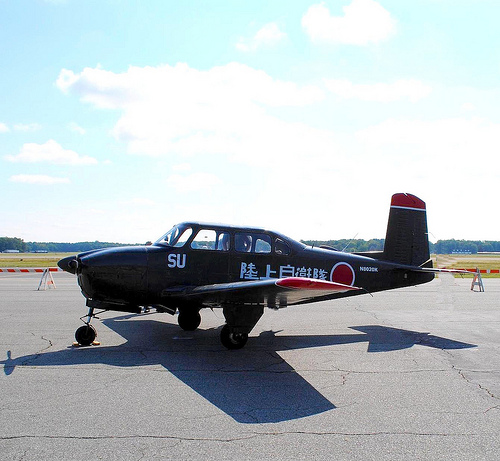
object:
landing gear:
[74, 325, 99, 348]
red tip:
[382, 189, 432, 214]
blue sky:
[0, 0, 500, 231]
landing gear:
[218, 321, 249, 353]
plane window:
[231, 230, 255, 253]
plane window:
[152, 221, 196, 248]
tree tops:
[0, 237, 8, 254]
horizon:
[0, 233, 500, 256]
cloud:
[297, 0, 400, 50]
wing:
[183, 274, 360, 299]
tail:
[384, 190, 433, 266]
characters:
[238, 260, 331, 286]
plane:
[57, 192, 483, 352]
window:
[189, 227, 231, 256]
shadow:
[0, 315, 478, 428]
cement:
[68, 427, 250, 448]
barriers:
[0, 266, 59, 273]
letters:
[164, 253, 177, 270]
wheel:
[220, 320, 249, 350]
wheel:
[174, 310, 204, 330]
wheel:
[72, 323, 100, 347]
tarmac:
[0, 268, 480, 460]